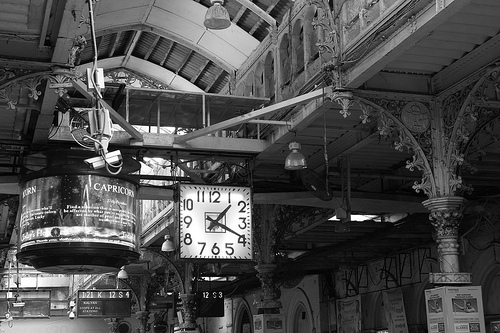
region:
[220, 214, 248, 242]
minute hand on the clock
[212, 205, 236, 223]
hour hand on clock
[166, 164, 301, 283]
black and white clock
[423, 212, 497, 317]
large pillar by clock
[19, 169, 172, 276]
circular billboard at station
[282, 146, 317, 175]
overhead ceiling light at station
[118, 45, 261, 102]
ceiling hanging on building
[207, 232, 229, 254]
six on the clock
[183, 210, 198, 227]
nine on the clock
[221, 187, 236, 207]
one on the clock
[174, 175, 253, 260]
square clock face with black hands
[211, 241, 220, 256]
number on clock face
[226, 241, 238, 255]
number on clock face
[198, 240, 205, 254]
number on clock face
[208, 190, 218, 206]
number on clock face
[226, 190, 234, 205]
number on clock face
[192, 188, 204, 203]
number on clock face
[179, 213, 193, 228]
number on clock face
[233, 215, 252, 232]
number on clock face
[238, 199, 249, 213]
number on clock face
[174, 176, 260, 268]
The clock is square shaped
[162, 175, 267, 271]
The clock is on the ceiling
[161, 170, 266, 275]
The clock is white in color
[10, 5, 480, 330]
Photo was taken indoors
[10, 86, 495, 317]
Photo is in black and white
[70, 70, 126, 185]
A recording camera is in the foreground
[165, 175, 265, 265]
Clock is around a black frame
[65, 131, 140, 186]
Camera is white in color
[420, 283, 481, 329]
Posters are in the foreground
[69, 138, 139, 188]
A side view of a camera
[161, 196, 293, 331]
a clock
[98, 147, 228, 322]
a clock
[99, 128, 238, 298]
a clock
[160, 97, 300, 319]
a clock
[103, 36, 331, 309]
a clock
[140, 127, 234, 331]
a clock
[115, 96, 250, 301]
a clock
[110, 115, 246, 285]
a clock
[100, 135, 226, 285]
a clock